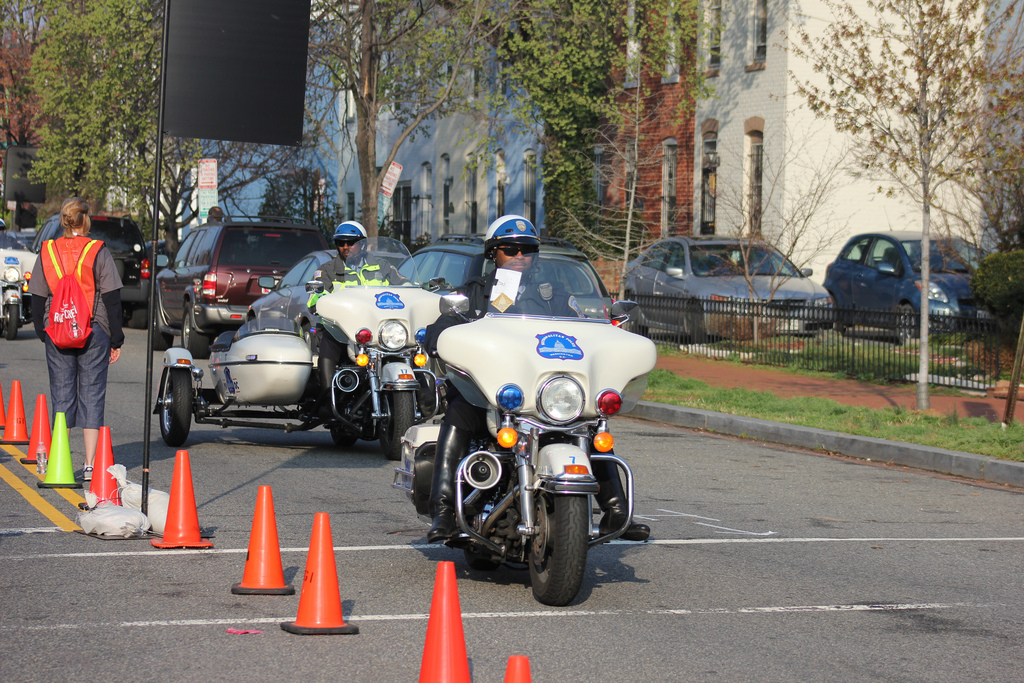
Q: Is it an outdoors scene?
A: Yes, it is outdoors.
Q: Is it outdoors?
A: Yes, it is outdoors.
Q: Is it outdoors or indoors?
A: It is outdoors.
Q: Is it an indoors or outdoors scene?
A: It is outdoors.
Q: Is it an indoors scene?
A: No, it is outdoors.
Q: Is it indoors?
A: No, it is outdoors.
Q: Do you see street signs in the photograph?
A: Yes, there is a street sign.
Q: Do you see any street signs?
A: Yes, there is a street sign.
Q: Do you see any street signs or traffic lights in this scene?
A: Yes, there is a street sign.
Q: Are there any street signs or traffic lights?
A: Yes, there is a street sign.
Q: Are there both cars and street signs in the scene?
A: Yes, there are both a street sign and a car.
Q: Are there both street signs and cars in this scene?
A: Yes, there are both a street sign and a car.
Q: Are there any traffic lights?
A: No, there are no traffic lights.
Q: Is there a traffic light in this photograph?
A: No, there are no traffic lights.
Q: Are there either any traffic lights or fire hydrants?
A: No, there are no traffic lights or fire hydrants.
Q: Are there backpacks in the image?
A: Yes, there is a backpack.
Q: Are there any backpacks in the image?
A: Yes, there is a backpack.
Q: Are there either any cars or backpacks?
A: Yes, there is a backpack.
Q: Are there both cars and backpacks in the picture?
A: Yes, there are both a backpack and a car.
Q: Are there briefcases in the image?
A: No, there are no briefcases.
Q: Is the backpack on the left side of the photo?
A: Yes, the backpack is on the left of the image.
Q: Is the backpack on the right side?
A: No, the backpack is on the left of the image.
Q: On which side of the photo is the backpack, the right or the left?
A: The backpack is on the left of the image.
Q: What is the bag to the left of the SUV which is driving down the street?
A: The bag is a backpack.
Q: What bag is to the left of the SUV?
A: The bag is a backpack.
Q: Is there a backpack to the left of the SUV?
A: Yes, there is a backpack to the left of the SUV.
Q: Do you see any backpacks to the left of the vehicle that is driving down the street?
A: Yes, there is a backpack to the left of the SUV.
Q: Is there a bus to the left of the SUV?
A: No, there is a backpack to the left of the SUV.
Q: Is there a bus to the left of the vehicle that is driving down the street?
A: No, there is a backpack to the left of the SUV.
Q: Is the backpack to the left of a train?
A: No, the backpack is to the left of a SUV.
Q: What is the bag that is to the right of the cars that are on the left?
A: The bag is a backpack.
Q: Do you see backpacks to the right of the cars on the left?
A: Yes, there is a backpack to the right of the cars.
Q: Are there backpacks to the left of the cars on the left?
A: No, the backpack is to the right of the cars.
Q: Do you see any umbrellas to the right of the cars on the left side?
A: No, there is a backpack to the right of the cars.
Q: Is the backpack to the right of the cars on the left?
A: Yes, the backpack is to the right of the cars.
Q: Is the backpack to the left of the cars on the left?
A: No, the backpack is to the right of the cars.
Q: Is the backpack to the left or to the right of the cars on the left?
A: The backpack is to the right of the cars.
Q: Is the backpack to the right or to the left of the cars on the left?
A: The backpack is to the right of the cars.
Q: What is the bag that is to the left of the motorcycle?
A: The bag is a backpack.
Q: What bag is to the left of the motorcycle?
A: The bag is a backpack.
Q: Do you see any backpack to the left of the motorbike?
A: Yes, there is a backpack to the left of the motorbike.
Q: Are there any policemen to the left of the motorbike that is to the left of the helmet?
A: No, there is a backpack to the left of the motorbike.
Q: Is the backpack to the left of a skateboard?
A: No, the backpack is to the left of the motorcycle.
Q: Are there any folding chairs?
A: No, there are no folding chairs.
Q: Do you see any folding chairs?
A: No, there are no folding chairs.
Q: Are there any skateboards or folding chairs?
A: No, there are no folding chairs or skateboards.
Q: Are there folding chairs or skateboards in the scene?
A: No, there are no folding chairs or skateboards.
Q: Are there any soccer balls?
A: No, there are no soccer balls.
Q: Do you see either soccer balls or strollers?
A: No, there are no soccer balls or strollers.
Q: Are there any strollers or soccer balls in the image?
A: No, there are no soccer balls or strollers.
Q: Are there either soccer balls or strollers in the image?
A: No, there are no soccer balls or strollers.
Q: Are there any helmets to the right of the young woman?
A: Yes, there are helmets to the right of the woman.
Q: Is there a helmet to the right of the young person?
A: Yes, there are helmets to the right of the woman.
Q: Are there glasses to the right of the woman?
A: No, there are helmets to the right of the woman.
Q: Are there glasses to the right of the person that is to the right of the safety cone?
A: No, there are helmets to the right of the woman.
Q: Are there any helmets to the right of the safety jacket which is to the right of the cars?
A: Yes, there are helmets to the right of the safety jacket.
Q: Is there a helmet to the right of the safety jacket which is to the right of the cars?
A: Yes, there are helmets to the right of the safety jacket.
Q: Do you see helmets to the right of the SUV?
A: Yes, there are helmets to the right of the SUV.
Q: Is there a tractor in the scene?
A: No, there are no tractors.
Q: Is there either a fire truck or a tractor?
A: No, there are no tractors or fire trucks.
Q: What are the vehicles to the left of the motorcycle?
A: The vehicles are cars.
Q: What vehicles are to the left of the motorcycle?
A: The vehicles are cars.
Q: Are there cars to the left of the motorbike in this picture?
A: Yes, there are cars to the left of the motorbike.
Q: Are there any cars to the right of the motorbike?
A: No, the cars are to the left of the motorbike.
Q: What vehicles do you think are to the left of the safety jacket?
A: The vehicles are cars.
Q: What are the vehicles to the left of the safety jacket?
A: The vehicles are cars.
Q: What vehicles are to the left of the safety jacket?
A: The vehicles are cars.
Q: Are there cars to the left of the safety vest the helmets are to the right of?
A: Yes, there are cars to the left of the safety vest.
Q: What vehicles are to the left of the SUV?
A: The vehicles are cars.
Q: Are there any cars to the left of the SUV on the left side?
A: Yes, there are cars to the left of the SUV.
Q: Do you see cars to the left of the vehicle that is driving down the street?
A: Yes, there are cars to the left of the SUV.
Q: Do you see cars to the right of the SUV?
A: No, the cars are to the left of the SUV.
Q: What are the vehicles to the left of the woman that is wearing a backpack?
A: The vehicles are cars.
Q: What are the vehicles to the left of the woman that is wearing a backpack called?
A: The vehicles are cars.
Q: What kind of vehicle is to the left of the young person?
A: The vehicles are cars.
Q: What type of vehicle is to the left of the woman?
A: The vehicles are cars.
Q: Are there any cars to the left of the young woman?
A: Yes, there are cars to the left of the woman.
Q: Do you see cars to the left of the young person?
A: Yes, there are cars to the left of the woman.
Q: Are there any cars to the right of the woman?
A: No, the cars are to the left of the woman.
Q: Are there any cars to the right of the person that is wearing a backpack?
A: No, the cars are to the left of the woman.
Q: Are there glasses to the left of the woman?
A: No, there are cars to the left of the woman.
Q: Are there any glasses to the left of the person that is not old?
A: No, there are cars to the left of the woman.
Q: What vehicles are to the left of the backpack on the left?
A: The vehicles are cars.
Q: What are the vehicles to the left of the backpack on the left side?
A: The vehicles are cars.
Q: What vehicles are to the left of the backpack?
A: The vehicles are cars.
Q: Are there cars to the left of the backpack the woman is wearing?
A: Yes, there are cars to the left of the backpack.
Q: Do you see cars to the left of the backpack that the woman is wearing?
A: Yes, there are cars to the left of the backpack.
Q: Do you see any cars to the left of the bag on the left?
A: Yes, there are cars to the left of the backpack.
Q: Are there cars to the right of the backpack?
A: No, the cars are to the left of the backpack.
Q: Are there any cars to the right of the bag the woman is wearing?
A: No, the cars are to the left of the backpack.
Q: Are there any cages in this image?
A: No, there are no cages.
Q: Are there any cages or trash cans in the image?
A: No, there are no cages or trash cans.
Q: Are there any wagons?
A: No, there are no wagons.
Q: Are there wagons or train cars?
A: No, there are no wagons or train cars.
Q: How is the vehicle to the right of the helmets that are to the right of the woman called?
A: The vehicle is a car.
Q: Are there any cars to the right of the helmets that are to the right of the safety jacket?
A: Yes, there is a car to the right of the helmets.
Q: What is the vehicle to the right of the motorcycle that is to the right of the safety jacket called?
A: The vehicle is a car.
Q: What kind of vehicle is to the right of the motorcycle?
A: The vehicle is a car.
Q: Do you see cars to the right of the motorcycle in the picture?
A: Yes, there is a car to the right of the motorcycle.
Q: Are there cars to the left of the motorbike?
A: No, the car is to the right of the motorbike.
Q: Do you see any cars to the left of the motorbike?
A: No, the car is to the right of the motorbike.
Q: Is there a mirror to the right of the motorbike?
A: No, there is a car to the right of the motorbike.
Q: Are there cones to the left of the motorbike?
A: Yes, there is a cone to the left of the motorbike.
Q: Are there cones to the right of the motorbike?
A: No, the cone is to the left of the motorbike.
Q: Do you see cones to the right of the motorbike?
A: No, the cone is to the left of the motorbike.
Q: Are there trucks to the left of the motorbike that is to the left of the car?
A: No, there is a cone to the left of the motorcycle.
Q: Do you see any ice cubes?
A: No, there are no ice cubes.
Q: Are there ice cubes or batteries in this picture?
A: No, there are no ice cubes or batteries.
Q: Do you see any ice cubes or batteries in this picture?
A: No, there are no ice cubes or batteries.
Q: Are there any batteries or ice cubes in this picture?
A: No, there are no ice cubes or batteries.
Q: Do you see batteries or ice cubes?
A: No, there are no ice cubes or batteries.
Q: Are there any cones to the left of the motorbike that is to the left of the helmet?
A: Yes, there is a cone to the left of the motorbike.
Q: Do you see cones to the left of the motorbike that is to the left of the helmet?
A: Yes, there is a cone to the left of the motorbike.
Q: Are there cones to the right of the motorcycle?
A: No, the cone is to the left of the motorcycle.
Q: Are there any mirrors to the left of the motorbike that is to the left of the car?
A: No, there is a cone to the left of the motorbike.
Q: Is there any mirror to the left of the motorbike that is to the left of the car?
A: No, there is a cone to the left of the motorbike.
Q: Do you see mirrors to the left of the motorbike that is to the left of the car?
A: No, there is a cone to the left of the motorbike.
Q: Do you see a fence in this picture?
A: Yes, there is a fence.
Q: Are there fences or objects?
A: Yes, there is a fence.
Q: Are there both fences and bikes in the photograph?
A: Yes, there are both a fence and bikes.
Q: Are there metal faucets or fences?
A: Yes, there is a metal fence.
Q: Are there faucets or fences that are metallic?
A: Yes, the fence is metallic.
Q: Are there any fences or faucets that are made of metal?
A: Yes, the fence is made of metal.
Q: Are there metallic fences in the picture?
A: Yes, there is a metal fence.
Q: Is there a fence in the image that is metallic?
A: Yes, there is a fence that is metallic.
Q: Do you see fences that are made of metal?
A: Yes, there is a fence that is made of metal.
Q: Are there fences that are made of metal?
A: Yes, there is a fence that is made of metal.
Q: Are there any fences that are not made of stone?
A: Yes, there is a fence that is made of metal.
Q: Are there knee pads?
A: No, there are no knee pads.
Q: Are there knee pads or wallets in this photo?
A: No, there are no knee pads or wallets.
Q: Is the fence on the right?
A: Yes, the fence is on the right of the image.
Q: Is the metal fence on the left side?
A: No, the fence is on the right of the image.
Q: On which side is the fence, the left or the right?
A: The fence is on the right of the image.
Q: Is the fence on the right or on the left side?
A: The fence is on the right of the image.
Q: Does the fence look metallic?
A: Yes, the fence is metallic.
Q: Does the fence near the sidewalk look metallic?
A: Yes, the fence is metallic.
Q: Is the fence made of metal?
A: Yes, the fence is made of metal.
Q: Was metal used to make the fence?
A: Yes, the fence is made of metal.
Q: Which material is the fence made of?
A: The fence is made of metal.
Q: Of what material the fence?
A: The fence is made of metal.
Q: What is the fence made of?
A: The fence is made of metal.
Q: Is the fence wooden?
A: No, the fence is metallic.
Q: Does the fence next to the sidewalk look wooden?
A: No, the fence is metallic.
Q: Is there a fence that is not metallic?
A: No, there is a fence but it is metallic.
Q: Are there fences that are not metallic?
A: No, there is a fence but it is metallic.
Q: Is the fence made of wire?
A: No, the fence is made of metal.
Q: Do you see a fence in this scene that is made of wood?
A: No, there is a fence but it is made of metal.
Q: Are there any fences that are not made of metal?
A: No, there is a fence but it is made of metal.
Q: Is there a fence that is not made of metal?
A: No, there is a fence but it is made of metal.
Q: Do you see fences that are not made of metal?
A: No, there is a fence but it is made of metal.